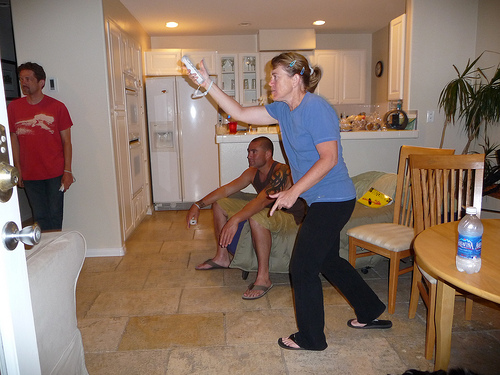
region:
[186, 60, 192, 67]
A remote control raised up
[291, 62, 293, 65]
Blue decoration in the hair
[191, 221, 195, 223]
Remote control facing front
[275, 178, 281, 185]
Tatoo on the arm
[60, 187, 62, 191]
Remote control held down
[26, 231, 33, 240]
A metallic door knob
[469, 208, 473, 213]
A white bottle top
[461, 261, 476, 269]
A bottle of water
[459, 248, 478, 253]
Label on water bottle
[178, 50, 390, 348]
a woman playing a video game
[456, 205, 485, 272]
a bottle of water on a table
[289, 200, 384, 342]
a woman wearing black pants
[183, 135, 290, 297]
a man sitting in an armchair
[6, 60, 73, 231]
a man standing against a wall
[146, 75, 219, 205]
a white fridge in a kitchen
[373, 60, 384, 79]
a black clock on a wall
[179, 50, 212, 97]
a woman holding a gaming controller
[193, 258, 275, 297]
a man wearing flip flops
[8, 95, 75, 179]
man wearing a red shirt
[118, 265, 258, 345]
brown stone floor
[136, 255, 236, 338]
lines on the floor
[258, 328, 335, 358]
black flip flops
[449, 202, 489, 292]
clear water bottle on table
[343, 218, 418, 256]
white seat on chair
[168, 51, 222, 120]
white remote in woman's hand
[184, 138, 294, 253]
man sitting on sofa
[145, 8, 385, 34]
lights in the ceiling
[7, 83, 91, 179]
man wearing red shirt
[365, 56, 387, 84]
clock on the wall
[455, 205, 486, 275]
a water can with blue color label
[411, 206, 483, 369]
water can is placed on the table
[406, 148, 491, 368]
a chair is kept behind the table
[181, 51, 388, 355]
two people are inside the home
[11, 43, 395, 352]
three people appears to be playing a game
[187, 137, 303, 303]
a guy is sitting on the couch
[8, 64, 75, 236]
a guy standing in red color t-shirt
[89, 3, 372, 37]
two lights turned on on the cieling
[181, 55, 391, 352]
a person in blue color t-shirt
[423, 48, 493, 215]
plants near the wall with green leaves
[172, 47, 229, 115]
woman holding remote control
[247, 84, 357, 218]
woman wearing blue shirt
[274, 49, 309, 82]
woman wearing blue hair clips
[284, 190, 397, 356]
woman wearing black pants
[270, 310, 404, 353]
woman wearing black shoes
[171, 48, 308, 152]
woman has arm extended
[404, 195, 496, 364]
water bottle on table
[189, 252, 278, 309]
male wearing tan shoes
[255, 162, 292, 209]
man with arm tattoo